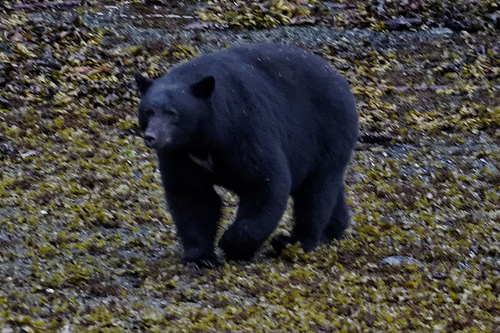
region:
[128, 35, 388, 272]
black bear walking on leaves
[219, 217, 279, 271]
large paw of bear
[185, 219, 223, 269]
large paw of bear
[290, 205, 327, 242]
large paw of bear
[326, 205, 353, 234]
large paw of bear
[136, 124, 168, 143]
nose of black bear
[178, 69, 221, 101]
ear of black bear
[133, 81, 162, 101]
ear of black bear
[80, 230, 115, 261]
patch of green leaves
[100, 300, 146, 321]
patch of green leaves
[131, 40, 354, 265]
the big black bear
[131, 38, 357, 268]
the black bear walking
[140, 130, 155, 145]
the nose on the bear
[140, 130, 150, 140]
the bear's black nose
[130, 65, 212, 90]
the bear's black ears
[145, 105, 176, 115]
the bear's eyes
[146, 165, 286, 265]
the bear's arms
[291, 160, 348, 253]
the bear's legs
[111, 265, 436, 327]
the ground the bear is walking on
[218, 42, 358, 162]
the bear's body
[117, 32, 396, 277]
The bear is walking.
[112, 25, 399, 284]
The bear is black.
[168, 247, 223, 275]
The bear's claws are visible.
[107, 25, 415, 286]
The bear is walking to the left.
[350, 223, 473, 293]
The ground is covered with rocks.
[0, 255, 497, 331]
The ground is cover with vegetation.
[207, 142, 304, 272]
The bear lifts his paw.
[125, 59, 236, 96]
The bear's ears are black.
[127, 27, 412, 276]
The bear is round.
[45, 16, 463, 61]
The ground behind the bear is rocky.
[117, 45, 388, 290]
bear walking on the ground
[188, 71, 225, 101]
ear on the bear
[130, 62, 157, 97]
ear on the bear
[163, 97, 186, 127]
eye on the bear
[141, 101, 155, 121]
eye on the bear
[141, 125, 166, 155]
nose on the bear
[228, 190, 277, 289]
leg on the bear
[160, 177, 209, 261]
leg on the bear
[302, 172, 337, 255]
leg on the bear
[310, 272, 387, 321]
plants on the ground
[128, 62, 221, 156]
the head of a bear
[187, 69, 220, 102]
the ear of a bear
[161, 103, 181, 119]
the eye of a bear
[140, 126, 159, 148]
the nose of a bear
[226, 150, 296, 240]
the leg of a bear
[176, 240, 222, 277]
the paw of a bear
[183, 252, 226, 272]
the claws of a bear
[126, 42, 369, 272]
a large black bear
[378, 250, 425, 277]
a gray rock on the ground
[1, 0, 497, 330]
a muddy leafy ground